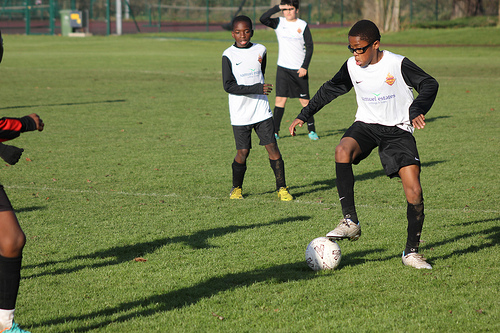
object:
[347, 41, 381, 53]
glasses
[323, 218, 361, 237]
foot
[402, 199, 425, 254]
shinguards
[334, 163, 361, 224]
shinguards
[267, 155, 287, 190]
shinguards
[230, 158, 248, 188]
shinguards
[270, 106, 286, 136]
shinguards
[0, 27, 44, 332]
boys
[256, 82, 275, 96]
hand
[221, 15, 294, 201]
body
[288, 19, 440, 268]
boy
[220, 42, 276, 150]
uniform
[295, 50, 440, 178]
uniform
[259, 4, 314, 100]
uniform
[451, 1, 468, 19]
tree trunk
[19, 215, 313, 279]
shadows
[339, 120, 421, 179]
shorts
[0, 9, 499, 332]
courts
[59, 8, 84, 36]
garbage cans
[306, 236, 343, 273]
ball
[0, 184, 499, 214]
white line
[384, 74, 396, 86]
logo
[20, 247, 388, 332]
shadows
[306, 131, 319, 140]
soccer cleat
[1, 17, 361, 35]
walkway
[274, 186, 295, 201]
shoe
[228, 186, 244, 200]
shoe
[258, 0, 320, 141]
boy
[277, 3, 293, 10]
hand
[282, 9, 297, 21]
face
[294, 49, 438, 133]
jersey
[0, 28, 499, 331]
grass